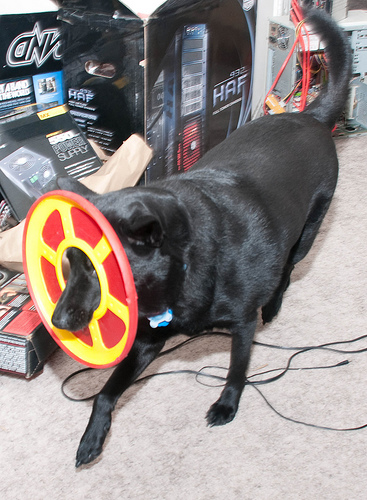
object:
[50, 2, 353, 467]
dog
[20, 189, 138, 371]
frisbee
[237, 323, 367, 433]
wire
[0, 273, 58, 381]
box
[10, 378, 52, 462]
floor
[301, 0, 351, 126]
tail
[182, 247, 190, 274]
collar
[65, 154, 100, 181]
letters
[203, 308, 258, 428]
leg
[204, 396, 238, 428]
paw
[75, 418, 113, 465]
paw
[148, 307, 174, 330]
tag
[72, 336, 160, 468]
leg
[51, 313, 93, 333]
nose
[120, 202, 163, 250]
ear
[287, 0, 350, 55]
tower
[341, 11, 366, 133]
case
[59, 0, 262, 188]
box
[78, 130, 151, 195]
bag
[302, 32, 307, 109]
wires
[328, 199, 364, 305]
carpet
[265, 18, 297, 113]
box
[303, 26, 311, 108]
cords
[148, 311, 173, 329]
silver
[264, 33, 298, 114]
cord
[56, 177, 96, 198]
ear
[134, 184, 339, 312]
side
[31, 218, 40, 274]
yellow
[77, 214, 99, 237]
red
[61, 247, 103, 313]
middle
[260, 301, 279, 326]
paw